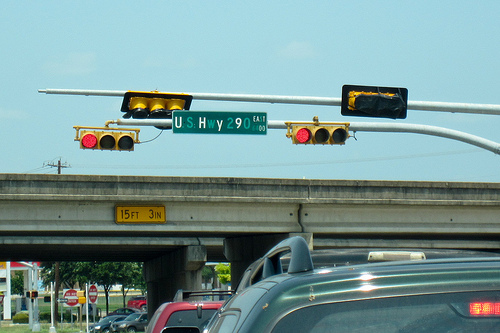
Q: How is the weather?
A: It is clear.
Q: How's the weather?
A: It is clear.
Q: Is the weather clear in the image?
A: Yes, it is clear.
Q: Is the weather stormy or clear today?
A: It is clear.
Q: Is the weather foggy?
A: No, it is clear.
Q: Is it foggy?
A: No, it is clear.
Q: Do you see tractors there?
A: No, there are no tractors.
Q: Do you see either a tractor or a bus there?
A: No, there are no tractors or buses.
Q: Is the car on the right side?
A: No, the car is on the left of the image.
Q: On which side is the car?
A: The car is on the left of the image.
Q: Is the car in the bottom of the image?
A: Yes, the car is in the bottom of the image.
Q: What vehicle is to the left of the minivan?
A: The vehicle is a car.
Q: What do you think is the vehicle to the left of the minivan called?
A: The vehicle is a car.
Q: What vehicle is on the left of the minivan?
A: The vehicle is a car.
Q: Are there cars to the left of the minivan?
A: Yes, there is a car to the left of the minivan.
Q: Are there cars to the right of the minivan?
A: No, the car is to the left of the minivan.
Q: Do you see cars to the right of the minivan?
A: No, the car is to the left of the minivan.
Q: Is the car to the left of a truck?
A: No, the car is to the left of the minivan.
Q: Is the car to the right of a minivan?
A: No, the car is to the left of a minivan.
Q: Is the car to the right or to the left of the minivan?
A: The car is to the left of the minivan.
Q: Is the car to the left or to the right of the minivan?
A: The car is to the left of the minivan.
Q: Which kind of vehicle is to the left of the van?
A: The vehicle is a car.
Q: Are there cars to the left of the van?
A: Yes, there is a car to the left of the van.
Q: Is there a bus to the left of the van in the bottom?
A: No, there is a car to the left of the van.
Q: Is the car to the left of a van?
A: Yes, the car is to the left of a van.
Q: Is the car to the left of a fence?
A: No, the car is to the left of a van.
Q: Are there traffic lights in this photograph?
A: Yes, there is a traffic light.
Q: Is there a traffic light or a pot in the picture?
A: Yes, there is a traffic light.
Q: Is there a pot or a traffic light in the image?
A: Yes, there is a traffic light.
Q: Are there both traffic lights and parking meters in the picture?
A: No, there is a traffic light but no parking meters.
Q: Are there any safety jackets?
A: No, there are no safety jackets.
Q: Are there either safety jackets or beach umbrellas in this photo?
A: No, there are no safety jackets or beach umbrellas.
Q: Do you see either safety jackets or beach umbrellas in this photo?
A: No, there are no safety jackets or beach umbrellas.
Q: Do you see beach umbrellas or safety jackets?
A: No, there are no safety jackets or beach umbrellas.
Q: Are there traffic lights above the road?
A: Yes, there is a traffic light above the road.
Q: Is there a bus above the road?
A: No, there is a traffic light above the road.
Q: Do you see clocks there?
A: No, there are no clocks.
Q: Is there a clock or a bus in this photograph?
A: No, there are no clocks or buses.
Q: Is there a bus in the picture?
A: No, there are no buses.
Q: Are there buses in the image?
A: No, there are no buses.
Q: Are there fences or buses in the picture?
A: No, there are no buses or fences.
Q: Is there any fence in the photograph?
A: No, there are no fences.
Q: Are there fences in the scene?
A: No, there are no fences.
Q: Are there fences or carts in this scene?
A: No, there are no fences or carts.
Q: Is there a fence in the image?
A: No, there are no fences.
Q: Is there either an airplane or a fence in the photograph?
A: No, there are no fences or airplanes.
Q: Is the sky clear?
A: Yes, the sky is clear.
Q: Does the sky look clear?
A: Yes, the sky is clear.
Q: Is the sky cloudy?
A: No, the sky is clear.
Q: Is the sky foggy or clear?
A: The sky is clear.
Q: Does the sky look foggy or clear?
A: The sky is clear.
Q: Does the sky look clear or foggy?
A: The sky is clear.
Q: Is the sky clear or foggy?
A: The sky is clear.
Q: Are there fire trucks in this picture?
A: No, there are no fire trucks.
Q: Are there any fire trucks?
A: No, there are no fire trucks.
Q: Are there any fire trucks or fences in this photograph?
A: No, there are no fire trucks or fences.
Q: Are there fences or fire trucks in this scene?
A: No, there are no fire trucks or fences.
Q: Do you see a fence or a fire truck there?
A: No, there are no fire trucks or fences.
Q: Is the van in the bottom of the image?
A: Yes, the van is in the bottom of the image.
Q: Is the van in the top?
A: No, the van is in the bottom of the image.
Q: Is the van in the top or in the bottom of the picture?
A: The van is in the bottom of the image.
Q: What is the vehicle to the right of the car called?
A: The vehicle is a van.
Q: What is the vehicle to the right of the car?
A: The vehicle is a van.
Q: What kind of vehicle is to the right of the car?
A: The vehicle is a van.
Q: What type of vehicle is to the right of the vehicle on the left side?
A: The vehicle is a van.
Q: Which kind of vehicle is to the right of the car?
A: The vehicle is a van.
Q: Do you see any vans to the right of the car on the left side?
A: Yes, there is a van to the right of the car.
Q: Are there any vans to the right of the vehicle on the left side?
A: Yes, there is a van to the right of the car.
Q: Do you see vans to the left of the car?
A: No, the van is to the right of the car.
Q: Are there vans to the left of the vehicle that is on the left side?
A: No, the van is to the right of the car.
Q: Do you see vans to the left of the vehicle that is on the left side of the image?
A: No, the van is to the right of the car.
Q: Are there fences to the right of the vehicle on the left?
A: No, there is a van to the right of the car.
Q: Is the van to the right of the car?
A: Yes, the van is to the right of the car.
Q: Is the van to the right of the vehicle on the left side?
A: Yes, the van is to the right of the car.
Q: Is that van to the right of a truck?
A: No, the van is to the right of the car.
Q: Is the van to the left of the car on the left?
A: No, the van is to the right of the car.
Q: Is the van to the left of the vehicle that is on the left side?
A: No, the van is to the right of the car.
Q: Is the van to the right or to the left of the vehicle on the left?
A: The van is to the right of the car.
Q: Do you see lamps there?
A: No, there are no lamps.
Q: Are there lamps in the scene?
A: No, there are no lamps.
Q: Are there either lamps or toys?
A: No, there are no lamps or toys.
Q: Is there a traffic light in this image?
A: Yes, there is a traffic light.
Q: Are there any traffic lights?
A: Yes, there is a traffic light.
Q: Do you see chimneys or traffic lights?
A: Yes, there is a traffic light.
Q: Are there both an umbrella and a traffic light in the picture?
A: No, there is a traffic light but no umbrellas.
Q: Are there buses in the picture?
A: No, there are no buses.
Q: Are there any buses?
A: No, there are no buses.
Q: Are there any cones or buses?
A: No, there are no buses or cones.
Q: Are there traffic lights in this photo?
A: Yes, there is a traffic light.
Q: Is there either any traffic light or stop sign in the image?
A: Yes, there is a traffic light.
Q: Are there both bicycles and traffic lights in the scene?
A: No, there is a traffic light but no bicycles.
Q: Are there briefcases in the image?
A: No, there are no briefcases.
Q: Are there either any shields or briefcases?
A: No, there are no briefcases or shields.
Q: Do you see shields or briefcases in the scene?
A: No, there are no briefcases or shields.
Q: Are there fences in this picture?
A: No, there are no fences.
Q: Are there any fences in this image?
A: No, there are no fences.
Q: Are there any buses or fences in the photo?
A: No, there are no fences or buses.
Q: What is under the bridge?
A: The sign is under the bridge.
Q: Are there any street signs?
A: Yes, there is a street sign.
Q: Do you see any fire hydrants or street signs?
A: Yes, there is a street sign.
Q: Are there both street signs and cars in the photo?
A: Yes, there are both a street sign and a car.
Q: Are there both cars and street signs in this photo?
A: Yes, there are both a street sign and a car.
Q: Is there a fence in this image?
A: No, there are no fences.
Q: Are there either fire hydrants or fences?
A: No, there are no fences or fire hydrants.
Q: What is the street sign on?
A: The street sign is on the pole.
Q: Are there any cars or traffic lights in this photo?
A: Yes, there is a traffic light.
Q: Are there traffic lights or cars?
A: Yes, there is a traffic light.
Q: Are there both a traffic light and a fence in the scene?
A: No, there is a traffic light but no fences.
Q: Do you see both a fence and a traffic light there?
A: No, there is a traffic light but no fences.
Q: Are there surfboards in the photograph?
A: No, there are no surfboards.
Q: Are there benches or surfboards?
A: No, there are no surfboards or benches.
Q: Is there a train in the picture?
A: No, there are no trains.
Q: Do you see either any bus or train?
A: No, there are no trains or buses.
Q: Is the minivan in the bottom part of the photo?
A: Yes, the minivan is in the bottom of the image.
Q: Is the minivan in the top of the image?
A: No, the minivan is in the bottom of the image.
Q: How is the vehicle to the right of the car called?
A: The vehicle is a minivan.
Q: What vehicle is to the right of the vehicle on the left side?
A: The vehicle is a minivan.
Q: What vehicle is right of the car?
A: The vehicle is a minivan.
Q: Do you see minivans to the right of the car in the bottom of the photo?
A: Yes, there is a minivan to the right of the car.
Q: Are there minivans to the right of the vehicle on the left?
A: Yes, there is a minivan to the right of the car.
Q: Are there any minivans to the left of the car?
A: No, the minivan is to the right of the car.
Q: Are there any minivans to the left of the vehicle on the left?
A: No, the minivan is to the right of the car.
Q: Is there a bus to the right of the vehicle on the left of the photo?
A: No, there is a minivan to the right of the car.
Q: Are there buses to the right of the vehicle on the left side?
A: No, there is a minivan to the right of the car.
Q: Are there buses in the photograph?
A: No, there are no buses.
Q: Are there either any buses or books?
A: No, there are no buses or books.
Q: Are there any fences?
A: No, there are no fences.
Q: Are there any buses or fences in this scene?
A: No, there are no fences or buses.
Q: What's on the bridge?
A: The sign is on the bridge.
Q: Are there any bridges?
A: Yes, there is a bridge.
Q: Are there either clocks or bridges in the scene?
A: Yes, there is a bridge.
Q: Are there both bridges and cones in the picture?
A: No, there is a bridge but no cones.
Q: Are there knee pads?
A: No, there are no knee pads.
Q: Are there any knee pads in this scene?
A: No, there are no knee pads.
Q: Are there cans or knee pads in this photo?
A: No, there are no knee pads or cans.